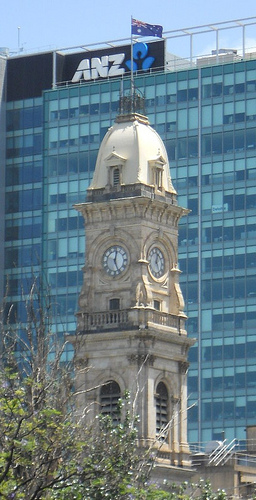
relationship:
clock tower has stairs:
[73, 77, 196, 469] [198, 436, 239, 468]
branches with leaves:
[10, 279, 130, 490] [3, 368, 84, 498]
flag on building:
[130, 17, 163, 41] [2, 17, 253, 293]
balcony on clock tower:
[79, 305, 184, 336] [63, 111, 197, 465]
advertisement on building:
[209, 203, 227, 213] [9, 40, 255, 388]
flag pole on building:
[15, 24, 22, 49] [1, 15, 252, 457]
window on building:
[200, 307, 210, 330] [0, 48, 254, 498]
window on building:
[202, 77, 211, 101] [1, 15, 252, 457]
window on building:
[212, 276, 223, 308] [1, 15, 252, 457]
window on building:
[221, 305, 235, 336] [1, 15, 252, 457]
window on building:
[222, 100, 236, 130] [1, 15, 252, 457]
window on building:
[221, 128, 233, 158] [1, 15, 252, 457]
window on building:
[187, 134, 199, 162] [1, 15, 252, 457]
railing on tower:
[73, 306, 187, 331] [76, 9, 195, 494]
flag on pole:
[130, 17, 163, 41] [129, 15, 134, 95]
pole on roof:
[130, 14, 135, 98] [115, 94, 149, 124]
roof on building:
[115, 94, 149, 124] [64, 92, 198, 466]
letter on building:
[70, 56, 91, 82] [1, 15, 252, 457]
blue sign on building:
[124, 42, 154, 68] [0, 48, 254, 498]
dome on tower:
[87, 112, 180, 196] [72, 92, 193, 463]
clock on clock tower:
[98, 242, 130, 279] [64, 77, 197, 469]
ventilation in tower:
[111, 166, 120, 189] [72, 92, 193, 463]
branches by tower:
[10, 279, 130, 490] [72, 92, 193, 463]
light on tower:
[144, 370, 160, 446] [61, 218, 198, 480]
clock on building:
[98, 242, 130, 279] [73, 76, 191, 497]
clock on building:
[147, 246, 164, 282] [73, 76, 191, 497]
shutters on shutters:
[155, 381, 172, 443] [155, 381, 172, 443]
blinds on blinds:
[97, 375, 126, 439] [97, 375, 126, 439]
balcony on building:
[191, 438, 254, 465] [0, 48, 254, 498]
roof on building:
[41, 50, 255, 87] [42, 56, 255, 461]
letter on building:
[70, 56, 91, 82] [0, 48, 254, 498]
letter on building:
[91, 53, 111, 79] [0, 48, 254, 498]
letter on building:
[107, 50, 126, 76] [0, 48, 254, 498]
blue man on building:
[128, 48, 150, 70] [1, 15, 252, 457]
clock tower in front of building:
[64, 77, 197, 469] [0, 13, 256, 497]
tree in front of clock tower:
[0, 271, 149, 498] [63, 111, 197, 465]